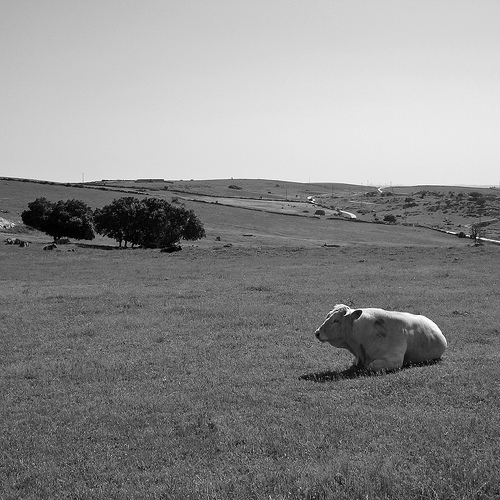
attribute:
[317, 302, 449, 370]
cow — white